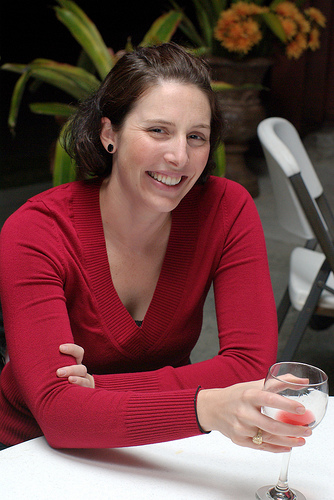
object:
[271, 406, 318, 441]
wine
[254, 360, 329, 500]
glass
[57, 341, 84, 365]
finger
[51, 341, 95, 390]
left hand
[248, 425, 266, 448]
ring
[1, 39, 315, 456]
woman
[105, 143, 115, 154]
earring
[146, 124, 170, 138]
eye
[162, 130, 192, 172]
nose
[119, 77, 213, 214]
face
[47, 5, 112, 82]
leaf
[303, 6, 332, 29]
flower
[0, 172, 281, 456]
sweater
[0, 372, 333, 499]
table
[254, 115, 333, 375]
chair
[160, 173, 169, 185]
tooth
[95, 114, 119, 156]
ear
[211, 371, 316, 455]
hand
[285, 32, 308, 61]
flower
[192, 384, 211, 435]
bracelet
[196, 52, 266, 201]
pot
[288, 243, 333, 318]
seating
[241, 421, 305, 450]
finger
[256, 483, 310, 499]
base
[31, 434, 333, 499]
shadow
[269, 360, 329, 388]
rim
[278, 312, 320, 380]
leg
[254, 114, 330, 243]
back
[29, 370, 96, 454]
elbow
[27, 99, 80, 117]
leaf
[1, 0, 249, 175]
plant